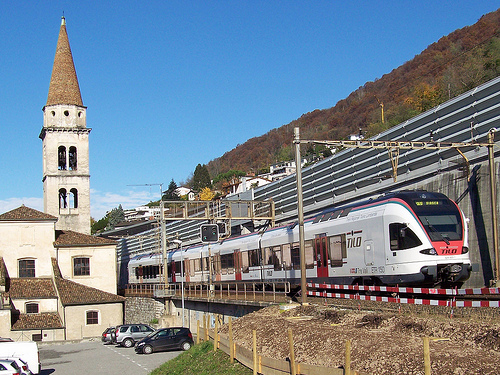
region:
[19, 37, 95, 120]
brown steeple on church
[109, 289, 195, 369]
cars parked near church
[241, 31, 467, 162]
green and brown trees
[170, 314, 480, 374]
brown posts near tracks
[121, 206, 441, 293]
red and white train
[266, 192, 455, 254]
red stripe on train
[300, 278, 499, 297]
red and white notice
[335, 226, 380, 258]
logo on side of train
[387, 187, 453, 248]
top of train is black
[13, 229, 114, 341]
tan walls of church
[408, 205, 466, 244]
window of a train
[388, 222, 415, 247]
window of a train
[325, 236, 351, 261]
window of a train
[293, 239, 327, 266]
window of a train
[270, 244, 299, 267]
window of a train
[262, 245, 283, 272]
window of a train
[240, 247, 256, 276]
window of a train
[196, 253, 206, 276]
window of a train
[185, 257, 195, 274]
window of a train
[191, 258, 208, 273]
window of a train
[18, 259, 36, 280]
window on a building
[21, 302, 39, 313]
window on a building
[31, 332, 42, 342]
window on a building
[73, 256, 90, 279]
window on a building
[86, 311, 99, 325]
window on a building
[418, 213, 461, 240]
window on a train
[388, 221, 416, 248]
window on a train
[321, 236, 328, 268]
window on a train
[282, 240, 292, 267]
window on a train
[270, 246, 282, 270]
window on a train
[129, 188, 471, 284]
white train sitting on the tracks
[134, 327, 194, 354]
black car in the parking area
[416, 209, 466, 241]
front windshield of the train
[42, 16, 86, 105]
brown steeple of the white building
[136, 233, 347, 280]
passenger windows on the right side of the train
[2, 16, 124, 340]
white building on the side of road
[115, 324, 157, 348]
silver car parked next to the black car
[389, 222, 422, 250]
front right windshield of the train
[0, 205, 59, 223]
brown roof of the building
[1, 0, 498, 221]
blue sky with white clouds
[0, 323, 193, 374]
the cars parked in the lot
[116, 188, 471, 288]
the train on the track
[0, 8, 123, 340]
the building near the train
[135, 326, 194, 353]
the black car parked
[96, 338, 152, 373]
the white lines on the ground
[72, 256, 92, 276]
the window on the building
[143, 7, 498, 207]
the mountain near the train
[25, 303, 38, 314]
the window on the building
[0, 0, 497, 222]
the blue sky with a little bit of clouds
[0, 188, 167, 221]
the clouds in the sky